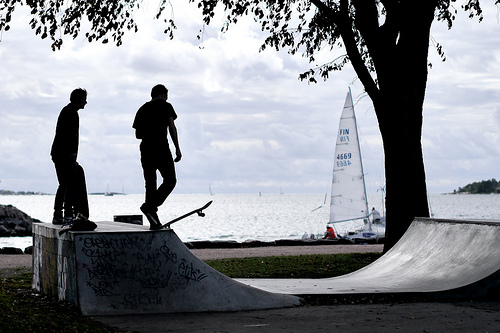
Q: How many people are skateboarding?
A: 2.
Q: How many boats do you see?
A: 1.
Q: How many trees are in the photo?
A: 1.